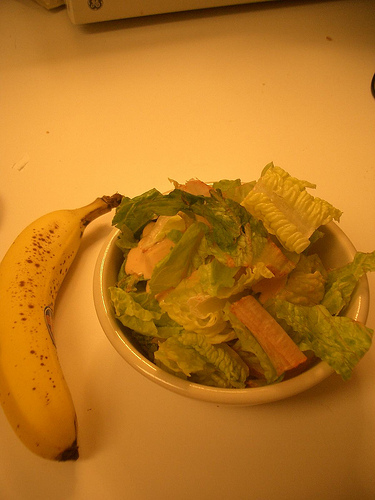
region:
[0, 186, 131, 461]
Banana with brown spots.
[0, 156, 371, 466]
Banana next to a bowl.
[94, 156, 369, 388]
Lettuce in a bowl.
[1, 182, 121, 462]
Sticker on a banana.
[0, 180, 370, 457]
White bowl next to a banana.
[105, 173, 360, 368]
Green vegetables in a bowl.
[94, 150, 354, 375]
Food in a bowl.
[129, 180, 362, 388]
Pieces of lettuce in a bowl.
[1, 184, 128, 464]
Banana with a sticker.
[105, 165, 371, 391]
Green food in a bowl.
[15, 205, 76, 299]
dark spots on a ripening banana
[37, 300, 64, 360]
sliver of label on inside curve of banana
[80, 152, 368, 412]
light-colored, circular ceramic bowl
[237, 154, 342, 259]
lettuce piece with rib in center and curls on the outside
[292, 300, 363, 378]
bite-size lettuce with crisscrossing of veins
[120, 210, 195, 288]
salads dressing concentrated in small section of salad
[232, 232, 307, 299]
lettuce edges which have started to turn brown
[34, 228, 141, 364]
curve of banana following the curve of the bowl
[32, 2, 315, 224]
flat surface between food and appliance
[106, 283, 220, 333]
ruffled edges of small bits of lettuce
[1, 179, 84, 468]
large yellow banana with skin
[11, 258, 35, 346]
spots on yellow banana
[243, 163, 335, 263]
large light green lettuce piece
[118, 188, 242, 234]
large dark green piece of lettuce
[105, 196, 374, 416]
round yellow bowl filled with lettuce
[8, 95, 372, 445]
large solid yellow surface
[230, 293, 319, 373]
brownish piece of lettuce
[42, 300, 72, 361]
yellow logo on banana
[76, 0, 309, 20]
section of unknown equipment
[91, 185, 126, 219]
brown tip of yellow banana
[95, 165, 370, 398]
Bowl of salad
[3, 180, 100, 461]
Ripped banana next to a bowl of salad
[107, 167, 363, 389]
Salad of lettuce with sauce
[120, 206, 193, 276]
Sauce for salad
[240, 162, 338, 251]
Piece of lettuce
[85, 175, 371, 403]
Yellow bowl with salad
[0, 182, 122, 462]
Banana with a sticker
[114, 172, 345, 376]
Pieces of lettuce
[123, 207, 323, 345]
lettuce with orange souce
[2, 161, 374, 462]
Bowl of salad and banana over table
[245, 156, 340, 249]
yellow colored romaine lettuce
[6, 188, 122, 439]
a banana with brown spots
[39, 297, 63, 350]
company logo on a banana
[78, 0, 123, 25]
company logo on an appliance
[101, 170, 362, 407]
salad in a bowl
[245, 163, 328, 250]
ruffles of a lettuce leaf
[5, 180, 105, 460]
a yellow banana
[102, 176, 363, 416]
a white glass bowl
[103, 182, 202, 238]
green leaf of lettuce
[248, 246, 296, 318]
browning lettuce